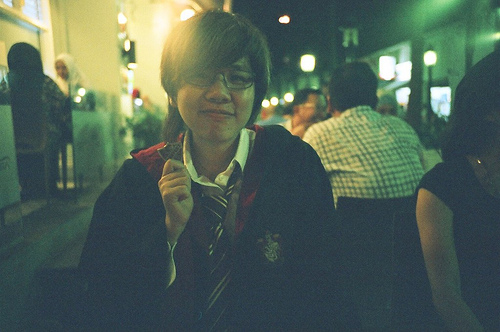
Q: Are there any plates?
A: No, there are no plates.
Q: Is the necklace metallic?
A: Yes, the necklace is metallic.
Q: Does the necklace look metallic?
A: Yes, the necklace is metallic.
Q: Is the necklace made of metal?
A: Yes, the necklace is made of metal.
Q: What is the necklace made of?
A: The necklace is made of metal.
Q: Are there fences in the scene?
A: No, there are no fences.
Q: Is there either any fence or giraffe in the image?
A: No, there are no fences or giraffes.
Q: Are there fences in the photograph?
A: No, there are no fences.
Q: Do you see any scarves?
A: Yes, there is a scarf.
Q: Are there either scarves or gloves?
A: Yes, there is a scarf.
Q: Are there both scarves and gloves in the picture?
A: No, there is a scarf but no gloves.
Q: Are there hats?
A: No, there are no hats.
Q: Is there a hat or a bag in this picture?
A: No, there are no hats or bags.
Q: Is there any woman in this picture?
A: Yes, there is a woman.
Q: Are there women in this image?
A: Yes, there is a woman.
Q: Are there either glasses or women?
A: Yes, there is a woman.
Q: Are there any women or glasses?
A: Yes, there is a woman.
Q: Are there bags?
A: No, there are no bags.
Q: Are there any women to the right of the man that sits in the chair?
A: Yes, there is a woman to the right of the man.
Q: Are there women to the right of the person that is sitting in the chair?
A: Yes, there is a woman to the right of the man.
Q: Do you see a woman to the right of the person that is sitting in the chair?
A: Yes, there is a woman to the right of the man.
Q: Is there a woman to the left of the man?
A: No, the woman is to the right of the man.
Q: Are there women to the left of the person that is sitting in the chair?
A: No, the woman is to the right of the man.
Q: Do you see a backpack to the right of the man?
A: No, there is a woman to the right of the man.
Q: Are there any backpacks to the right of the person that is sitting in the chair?
A: No, there is a woman to the right of the man.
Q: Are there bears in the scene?
A: No, there are no bears.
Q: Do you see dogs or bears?
A: No, there are no bears or dogs.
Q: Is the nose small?
A: Yes, the nose is small.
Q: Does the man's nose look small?
A: Yes, the nose is small.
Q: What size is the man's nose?
A: The nose is small.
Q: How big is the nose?
A: The nose is small.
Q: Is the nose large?
A: No, the nose is small.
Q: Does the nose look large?
A: No, the nose is small.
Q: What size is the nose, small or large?
A: The nose is small.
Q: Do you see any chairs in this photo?
A: Yes, there is a chair.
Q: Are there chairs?
A: Yes, there is a chair.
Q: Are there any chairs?
A: Yes, there is a chair.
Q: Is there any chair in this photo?
A: Yes, there is a chair.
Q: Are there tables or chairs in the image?
A: Yes, there is a chair.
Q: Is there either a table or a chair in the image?
A: Yes, there is a chair.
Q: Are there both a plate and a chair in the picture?
A: No, there is a chair but no plates.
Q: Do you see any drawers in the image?
A: No, there are no drawers.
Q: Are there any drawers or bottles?
A: No, there are no drawers or bottles.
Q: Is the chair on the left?
A: Yes, the chair is on the left of the image.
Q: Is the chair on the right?
A: No, the chair is on the left of the image.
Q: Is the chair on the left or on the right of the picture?
A: The chair is on the left of the image.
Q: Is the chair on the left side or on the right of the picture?
A: The chair is on the left of the image.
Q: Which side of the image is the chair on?
A: The chair is on the left of the image.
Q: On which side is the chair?
A: The chair is on the left of the image.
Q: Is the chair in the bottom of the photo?
A: Yes, the chair is in the bottom of the image.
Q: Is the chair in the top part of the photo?
A: No, the chair is in the bottom of the image.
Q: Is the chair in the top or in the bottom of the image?
A: The chair is in the bottom of the image.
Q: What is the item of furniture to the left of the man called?
A: The piece of furniture is a chair.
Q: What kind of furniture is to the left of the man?
A: The piece of furniture is a chair.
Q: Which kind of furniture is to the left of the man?
A: The piece of furniture is a chair.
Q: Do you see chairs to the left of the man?
A: Yes, there is a chair to the left of the man.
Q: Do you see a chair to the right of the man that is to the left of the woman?
A: No, the chair is to the left of the man.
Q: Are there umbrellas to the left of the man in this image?
A: No, there is a chair to the left of the man.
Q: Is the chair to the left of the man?
A: Yes, the chair is to the left of the man.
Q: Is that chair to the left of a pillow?
A: No, the chair is to the left of the man.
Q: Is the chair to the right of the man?
A: No, the chair is to the left of the man.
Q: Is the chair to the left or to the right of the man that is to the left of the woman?
A: The chair is to the left of the man.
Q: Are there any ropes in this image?
A: No, there are no ropes.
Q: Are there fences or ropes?
A: No, there are no ropes or fences.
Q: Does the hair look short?
A: Yes, the hair is short.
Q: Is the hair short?
A: Yes, the hair is short.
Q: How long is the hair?
A: The hair is short.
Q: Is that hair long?
A: No, the hair is short.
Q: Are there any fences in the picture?
A: No, there are no fences.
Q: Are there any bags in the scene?
A: No, there are no bags.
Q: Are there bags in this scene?
A: No, there are no bags.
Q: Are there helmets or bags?
A: No, there are no bags or helmets.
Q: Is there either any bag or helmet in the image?
A: No, there are no bags or helmets.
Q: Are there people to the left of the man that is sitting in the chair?
A: Yes, there is a person to the left of the man.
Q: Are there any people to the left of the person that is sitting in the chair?
A: Yes, there is a person to the left of the man.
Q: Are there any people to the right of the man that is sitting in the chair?
A: No, the person is to the left of the man.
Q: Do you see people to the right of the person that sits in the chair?
A: No, the person is to the left of the man.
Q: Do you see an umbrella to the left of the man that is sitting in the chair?
A: No, there is a person to the left of the man.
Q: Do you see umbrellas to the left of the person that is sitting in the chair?
A: No, there is a person to the left of the man.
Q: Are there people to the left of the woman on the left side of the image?
A: Yes, there is a person to the left of the woman.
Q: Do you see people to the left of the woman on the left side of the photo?
A: Yes, there is a person to the left of the woman.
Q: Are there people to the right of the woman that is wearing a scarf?
A: No, the person is to the left of the woman.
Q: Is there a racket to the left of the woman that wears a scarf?
A: No, there is a person to the left of the woman.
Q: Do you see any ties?
A: Yes, there is a tie.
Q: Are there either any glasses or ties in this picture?
A: Yes, there is a tie.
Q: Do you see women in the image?
A: Yes, there is a woman.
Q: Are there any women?
A: Yes, there is a woman.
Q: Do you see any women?
A: Yes, there is a woman.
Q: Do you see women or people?
A: Yes, there is a woman.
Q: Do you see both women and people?
A: Yes, there are both a woman and a person.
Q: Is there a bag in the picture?
A: No, there are no bags.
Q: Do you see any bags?
A: No, there are no bags.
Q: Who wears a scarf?
A: The woman wears a scarf.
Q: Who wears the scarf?
A: The woman wears a scarf.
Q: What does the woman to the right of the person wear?
A: The woman wears a scarf.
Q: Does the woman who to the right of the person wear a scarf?
A: Yes, the woman wears a scarf.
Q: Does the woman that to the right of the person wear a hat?
A: No, the woman wears a scarf.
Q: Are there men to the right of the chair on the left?
A: Yes, there is a man to the right of the chair.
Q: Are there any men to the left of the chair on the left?
A: No, the man is to the right of the chair.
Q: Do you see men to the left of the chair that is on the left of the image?
A: No, the man is to the right of the chair.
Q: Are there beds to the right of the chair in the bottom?
A: No, there is a man to the right of the chair.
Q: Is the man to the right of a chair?
A: Yes, the man is to the right of a chair.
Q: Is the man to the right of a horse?
A: No, the man is to the right of a chair.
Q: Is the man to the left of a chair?
A: No, the man is to the right of a chair.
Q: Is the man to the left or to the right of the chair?
A: The man is to the right of the chair.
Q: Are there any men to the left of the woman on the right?
A: Yes, there is a man to the left of the woman.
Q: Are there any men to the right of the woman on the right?
A: No, the man is to the left of the woman.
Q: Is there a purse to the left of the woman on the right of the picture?
A: No, there is a man to the left of the woman.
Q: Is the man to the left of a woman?
A: Yes, the man is to the left of a woman.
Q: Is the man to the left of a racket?
A: No, the man is to the left of a woman.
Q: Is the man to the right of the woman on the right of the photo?
A: No, the man is to the left of the woman.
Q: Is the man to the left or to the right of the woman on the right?
A: The man is to the left of the woman.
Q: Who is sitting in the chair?
A: The man is sitting in the chair.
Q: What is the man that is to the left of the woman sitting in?
A: The man is sitting in the chair.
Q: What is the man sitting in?
A: The man is sitting in the chair.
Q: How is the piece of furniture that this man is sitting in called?
A: The piece of furniture is a chair.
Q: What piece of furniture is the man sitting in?
A: The man is sitting in the chair.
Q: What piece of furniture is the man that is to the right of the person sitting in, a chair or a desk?
A: The man is sitting in a chair.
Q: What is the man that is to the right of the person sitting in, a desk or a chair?
A: The man is sitting in a chair.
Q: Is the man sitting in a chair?
A: Yes, the man is sitting in a chair.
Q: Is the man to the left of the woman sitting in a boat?
A: No, the man is sitting in a chair.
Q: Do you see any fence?
A: No, there are no fences.